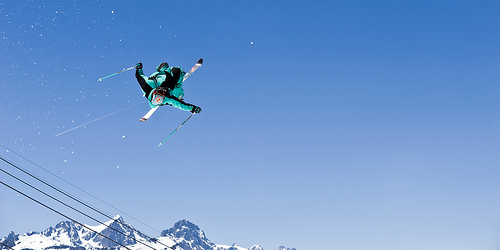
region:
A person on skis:
[135, 58, 205, 124]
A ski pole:
[95, 62, 142, 85]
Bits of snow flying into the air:
[6, 5, 143, 149]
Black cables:
[0, 148, 166, 248]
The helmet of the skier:
[147, 89, 167, 109]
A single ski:
[138, 57, 204, 122]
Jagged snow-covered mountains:
[0, 208, 289, 248]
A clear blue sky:
[0, 0, 492, 245]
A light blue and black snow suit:
[135, 62, 196, 113]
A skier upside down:
[127, 55, 204, 133]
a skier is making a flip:
[114, 47, 219, 135]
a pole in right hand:
[151, 102, 203, 154]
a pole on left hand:
[94, 54, 142, 84]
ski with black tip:
[181, 53, 207, 87]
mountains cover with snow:
[8, 206, 284, 248]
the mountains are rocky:
[4, 206, 307, 248]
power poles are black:
[0, 147, 177, 248]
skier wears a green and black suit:
[129, 52, 203, 124]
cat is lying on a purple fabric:
[164, 92, 205, 117]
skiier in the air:
[91, 43, 226, 145]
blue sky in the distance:
[316, 22, 443, 136]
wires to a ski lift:
[13, 160, 78, 222]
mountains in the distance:
[22, 211, 227, 248]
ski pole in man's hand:
[94, 65, 134, 88]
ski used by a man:
[183, 48, 208, 80]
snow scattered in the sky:
[100, 7, 122, 23]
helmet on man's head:
[143, 88, 166, 106]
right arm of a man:
[176, 94, 207, 118]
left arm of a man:
[132, 58, 152, 93]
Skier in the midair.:
[93, 53, 206, 152]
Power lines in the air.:
[0, 135, 175, 249]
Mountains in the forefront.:
[1, 208, 303, 248]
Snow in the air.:
[0, 0, 150, 185]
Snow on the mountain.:
[0, 208, 302, 248]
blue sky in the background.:
[0, 0, 497, 248]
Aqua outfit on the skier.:
[128, 54, 203, 125]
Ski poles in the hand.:
[94, 58, 146, 85]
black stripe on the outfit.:
[130, 60, 153, 94]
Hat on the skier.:
[148, 85, 165, 111]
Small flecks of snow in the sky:
[2, 6, 89, 111]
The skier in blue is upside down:
[95, 36, 233, 153]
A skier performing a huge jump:
[86, 44, 231, 154]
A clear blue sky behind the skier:
[278, 19, 483, 214]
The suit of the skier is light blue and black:
[132, 54, 199, 111]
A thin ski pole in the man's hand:
[154, 111, 202, 153]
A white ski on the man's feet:
[129, 57, 206, 126]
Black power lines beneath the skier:
[1, 150, 146, 245]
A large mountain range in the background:
[12, 208, 284, 248]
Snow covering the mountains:
[4, 205, 243, 247]